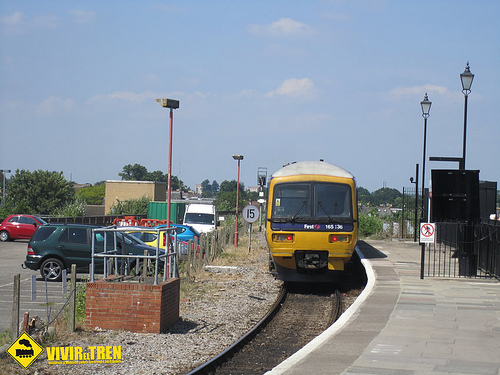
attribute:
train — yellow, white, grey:
[262, 157, 361, 282]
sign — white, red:
[416, 221, 436, 245]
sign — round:
[240, 202, 261, 226]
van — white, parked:
[178, 199, 219, 235]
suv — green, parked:
[22, 220, 168, 279]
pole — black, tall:
[418, 117, 429, 283]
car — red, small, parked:
[0, 213, 50, 240]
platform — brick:
[263, 237, 499, 374]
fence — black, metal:
[415, 221, 499, 280]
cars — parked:
[2, 200, 220, 282]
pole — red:
[164, 107, 174, 232]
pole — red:
[233, 161, 244, 246]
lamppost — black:
[415, 85, 430, 278]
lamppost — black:
[451, 61, 476, 174]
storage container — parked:
[144, 196, 183, 227]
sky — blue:
[1, 1, 499, 193]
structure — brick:
[85, 274, 180, 333]